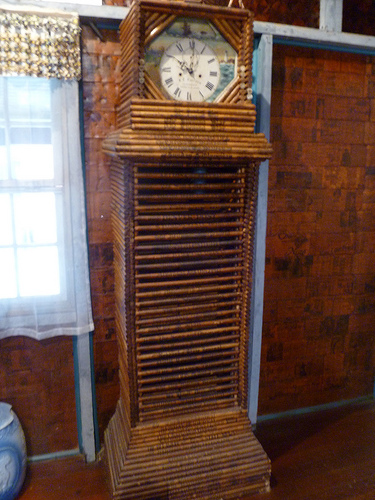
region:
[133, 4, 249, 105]
it is a wallclock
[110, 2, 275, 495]
wall clock mounted on wooden stand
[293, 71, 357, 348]
it is an brown color wall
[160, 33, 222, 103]
clock dial is white color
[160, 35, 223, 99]
clock dial is roman letters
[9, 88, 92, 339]
white color window screen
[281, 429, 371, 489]
brown color floor sheet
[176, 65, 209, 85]
clock have two key holes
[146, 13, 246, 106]
photo taken at 10 clock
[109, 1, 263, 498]
wooden clock holder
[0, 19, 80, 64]
silver and gold decorations on a curtain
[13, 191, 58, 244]
the pane in a window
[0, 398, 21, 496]
a ceramic container on the floor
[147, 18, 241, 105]
the face of a clock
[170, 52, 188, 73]
the hour hand of a clock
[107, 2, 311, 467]
a clock against a wall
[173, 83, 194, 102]
roman numerals on a clockface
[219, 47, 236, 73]
a light house on a clock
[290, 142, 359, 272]
brown cork walls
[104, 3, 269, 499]
A wood clock that goes from the floor clear up past the window.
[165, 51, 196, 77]
Big and little hands of a clock.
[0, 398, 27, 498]
A blue and white vase to the left of a clock.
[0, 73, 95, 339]
A white curtain over the window.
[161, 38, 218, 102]
A small white clock face.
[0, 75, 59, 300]
Eight visible glass panes of a window through the curtain.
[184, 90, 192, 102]
VI upside down on a clock face.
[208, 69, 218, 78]
III on a clock face that represents a 3.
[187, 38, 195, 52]
XII on the top of a clock face that means 12.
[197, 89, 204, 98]
V on a clock face that means 5.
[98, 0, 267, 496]
wooden grandfather clock against the wall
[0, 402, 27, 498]
blue and white vase on the floor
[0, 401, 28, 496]
white pot with blue designs on it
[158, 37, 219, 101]
clock with roman numerals on it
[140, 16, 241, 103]
clock with duck designs on it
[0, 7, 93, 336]
window with white curtains on it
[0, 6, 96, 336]
white curtains over the window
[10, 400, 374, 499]
brown hardwood floor with a clock on it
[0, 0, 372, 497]
wall with brown tiles on it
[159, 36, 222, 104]
clock set to 10:00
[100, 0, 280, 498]
a clock on a support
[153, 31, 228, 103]
a white clock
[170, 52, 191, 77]
hour hand of clock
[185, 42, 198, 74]
minute hand of clock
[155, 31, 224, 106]
clock has roman numerals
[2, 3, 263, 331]
a window on left side a clock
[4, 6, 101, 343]
window is cover with a curtain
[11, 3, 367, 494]
a clock in front a wall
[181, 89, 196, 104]
number VI of clock